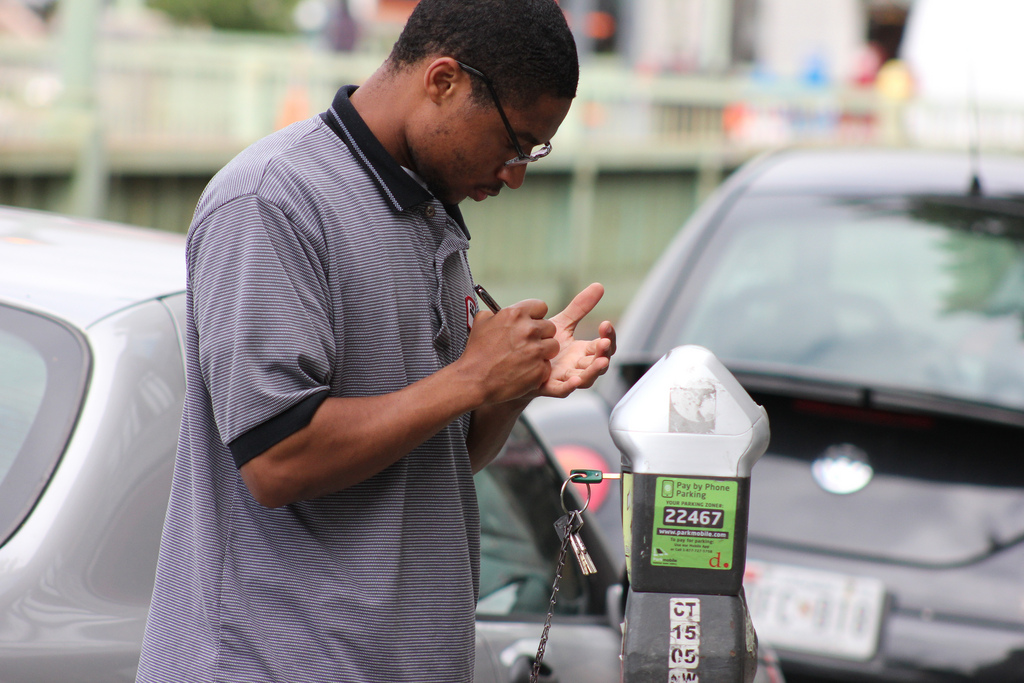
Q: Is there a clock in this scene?
A: No, there are no clocks.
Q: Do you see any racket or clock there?
A: No, there are no clocks or rackets.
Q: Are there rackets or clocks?
A: No, there are no clocks or rackets.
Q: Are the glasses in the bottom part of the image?
A: No, the glasses are in the top of the image.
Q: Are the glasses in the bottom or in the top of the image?
A: The glasses are in the top of the image.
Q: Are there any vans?
A: No, there are no vans.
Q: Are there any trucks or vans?
A: No, there are no vans or trucks.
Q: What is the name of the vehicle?
A: The vehicle is a car.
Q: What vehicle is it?
A: The vehicle is a car.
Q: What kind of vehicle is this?
A: This is a car.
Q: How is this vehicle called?
A: This is a car.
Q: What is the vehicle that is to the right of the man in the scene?
A: The vehicle is a car.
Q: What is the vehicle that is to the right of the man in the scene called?
A: The vehicle is a car.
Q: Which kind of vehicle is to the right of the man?
A: The vehicle is a car.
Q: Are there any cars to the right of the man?
A: Yes, there is a car to the right of the man.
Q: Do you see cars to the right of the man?
A: Yes, there is a car to the right of the man.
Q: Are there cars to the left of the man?
A: No, the car is to the right of the man.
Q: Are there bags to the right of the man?
A: No, there is a car to the right of the man.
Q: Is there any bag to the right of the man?
A: No, there is a car to the right of the man.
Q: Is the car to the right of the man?
A: Yes, the car is to the right of the man.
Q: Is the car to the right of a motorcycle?
A: No, the car is to the right of the man.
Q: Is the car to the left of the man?
A: No, the car is to the right of the man.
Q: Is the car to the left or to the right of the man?
A: The car is to the right of the man.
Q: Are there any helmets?
A: No, there are no helmets.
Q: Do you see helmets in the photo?
A: No, there are no helmets.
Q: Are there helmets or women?
A: No, there are no helmets or women.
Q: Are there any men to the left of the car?
A: Yes, there is a man to the left of the car.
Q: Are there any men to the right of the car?
A: No, the man is to the left of the car.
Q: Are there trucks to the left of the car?
A: No, there is a man to the left of the car.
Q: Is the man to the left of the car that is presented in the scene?
A: Yes, the man is to the left of the car.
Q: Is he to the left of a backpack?
A: No, the man is to the left of the car.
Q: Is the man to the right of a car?
A: No, the man is to the left of a car.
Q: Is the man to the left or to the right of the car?
A: The man is to the left of the car.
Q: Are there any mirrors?
A: No, there are no mirrors.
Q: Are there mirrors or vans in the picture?
A: No, there are no mirrors or vans.